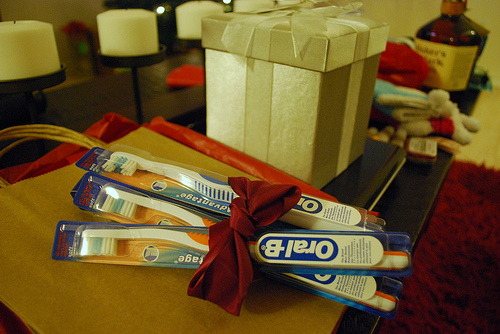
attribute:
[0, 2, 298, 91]
candles — white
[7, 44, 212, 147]
candle holders — black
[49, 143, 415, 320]
toothbrushes — blue, white, wrapped, new, tied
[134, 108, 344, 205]
tissue — red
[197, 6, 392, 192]
gift box — gold, here, wrapped, square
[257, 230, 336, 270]
brand — oral b, oral-b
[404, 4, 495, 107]
liquor bottle — maker's mark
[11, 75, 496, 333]
table — brown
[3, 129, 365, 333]
gift bags — yellow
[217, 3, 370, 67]
bow — white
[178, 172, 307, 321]
red bow — tied, here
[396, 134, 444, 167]
altoids — here, red, white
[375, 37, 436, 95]
clothing — here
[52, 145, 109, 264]
background — blue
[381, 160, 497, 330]
rug — red